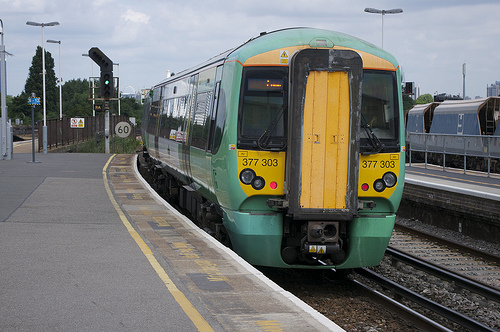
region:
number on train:
[349, 156, 399, 169]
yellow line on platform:
[118, 156, 194, 330]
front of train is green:
[234, 193, 384, 269]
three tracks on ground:
[408, 249, 495, 330]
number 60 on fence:
[87, 110, 132, 137]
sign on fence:
[64, 111, 92, 135]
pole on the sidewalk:
[21, 90, 45, 169]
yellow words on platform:
[168, 220, 232, 300]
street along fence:
[9, 136, 29, 152]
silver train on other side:
[412, 105, 499, 156]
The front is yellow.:
[297, 57, 353, 215]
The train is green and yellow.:
[114, 32, 414, 264]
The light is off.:
[232, 164, 266, 196]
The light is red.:
[265, 173, 286, 194]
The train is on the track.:
[114, 56, 496, 312]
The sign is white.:
[57, 105, 89, 130]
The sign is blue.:
[28, 91, 40, 108]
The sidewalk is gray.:
[7, 137, 297, 329]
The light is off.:
[357, 2, 411, 19]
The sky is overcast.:
[15, 9, 497, 91]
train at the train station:
[125, 51, 433, 316]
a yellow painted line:
[104, 188, 196, 328]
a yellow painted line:
[135, 245, 210, 329]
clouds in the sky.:
[120, 8, 143, 34]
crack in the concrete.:
[64, 248, 107, 305]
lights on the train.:
[242, 170, 262, 187]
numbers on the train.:
[260, 157, 278, 167]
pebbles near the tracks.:
[340, 300, 360, 322]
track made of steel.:
[401, 304, 431, 325]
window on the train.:
[245, 100, 276, 132]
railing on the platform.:
[436, 138, 466, 166]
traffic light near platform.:
[98, 74, 112, 104]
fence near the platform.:
[45, 123, 62, 143]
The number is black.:
[237, 156, 249, 167]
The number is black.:
[246, 154, 254, 168]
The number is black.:
[251, 154, 262, 169]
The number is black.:
[259, 154, 268, 169]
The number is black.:
[271, 156, 281, 170]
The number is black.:
[115, 120, 124, 137]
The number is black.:
[358, 156, 369, 171]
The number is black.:
[366, 155, 373, 170]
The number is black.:
[371, 156, 381, 171]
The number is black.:
[376, 155, 386, 172]